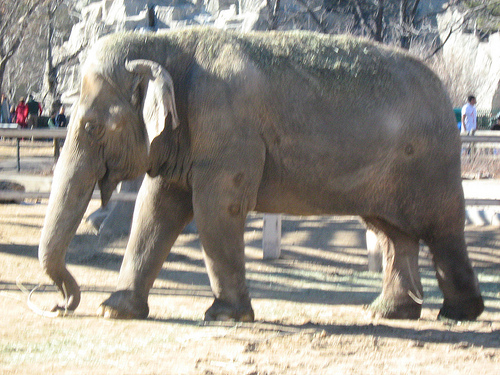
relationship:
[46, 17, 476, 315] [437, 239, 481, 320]
elephant has legs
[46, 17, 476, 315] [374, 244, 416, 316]
elephant has legs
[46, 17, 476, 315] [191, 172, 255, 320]
elephant has legs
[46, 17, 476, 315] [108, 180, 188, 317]
elephant has legs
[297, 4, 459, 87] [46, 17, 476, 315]
tree behind elephant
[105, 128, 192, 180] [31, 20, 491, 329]
skin on elephant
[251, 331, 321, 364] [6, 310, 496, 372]
dirt on ground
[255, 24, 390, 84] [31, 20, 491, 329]
hair on elephant